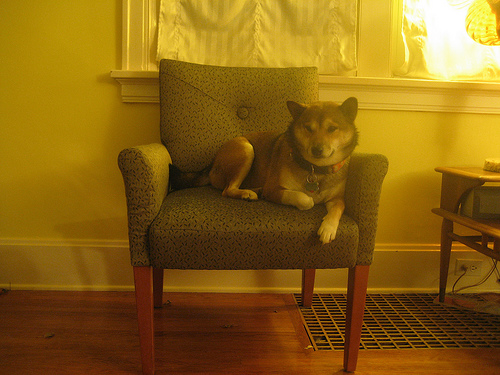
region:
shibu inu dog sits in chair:
[161, 94, 355, 238]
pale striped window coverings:
[161, 2, 356, 70]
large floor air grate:
[293, 288, 496, 352]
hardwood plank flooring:
[2, 291, 498, 372]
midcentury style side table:
[437, 163, 498, 307]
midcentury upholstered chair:
[117, 62, 375, 370]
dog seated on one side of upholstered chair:
[120, 56, 392, 369]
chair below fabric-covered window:
[95, 4, 392, 367]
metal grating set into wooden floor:
[5, 282, 496, 369]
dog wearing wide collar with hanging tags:
[281, 120, 353, 196]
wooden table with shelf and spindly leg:
[426, 154, 496, 311]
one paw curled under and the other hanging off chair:
[265, 175, 346, 246]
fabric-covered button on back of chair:
[158, 59, 320, 180]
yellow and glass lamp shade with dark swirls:
[462, 1, 497, 44]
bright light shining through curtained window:
[400, 2, 497, 80]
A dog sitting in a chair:
[118, 56, 391, 372]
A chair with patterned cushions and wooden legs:
[115, 58, 386, 374]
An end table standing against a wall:
[433, 152, 499, 315]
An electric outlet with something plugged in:
[450, 254, 486, 283]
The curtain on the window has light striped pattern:
[116, 10, 382, 85]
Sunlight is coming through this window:
[371, 10, 499, 92]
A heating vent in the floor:
[276, 281, 499, 364]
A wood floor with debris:
[1, 273, 338, 374]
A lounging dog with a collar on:
[167, 98, 366, 245]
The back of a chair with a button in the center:
[143, 56, 328, 181]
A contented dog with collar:
[168, 95, 364, 241]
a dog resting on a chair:
[109, 55, 390, 371]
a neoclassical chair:
[108, 55, 393, 374]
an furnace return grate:
[280, 275, 497, 362]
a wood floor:
[2, 281, 309, 371]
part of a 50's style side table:
[430, 145, 495, 330]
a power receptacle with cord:
[436, 258, 493, 296]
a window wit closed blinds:
[99, 26, 364, 112]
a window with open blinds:
[378, 24, 496, 99]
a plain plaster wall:
[5, 23, 109, 231]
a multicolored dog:
[167, 98, 359, 243]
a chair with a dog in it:
[114, 55, 391, 374]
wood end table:
[430, 152, 498, 305]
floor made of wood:
[3, 283, 496, 370]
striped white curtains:
[151, 0, 364, 84]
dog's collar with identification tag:
[287, 142, 351, 195]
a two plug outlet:
[453, 254, 484, 280]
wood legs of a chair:
[127, 255, 368, 372]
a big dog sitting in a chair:
[135, 60, 387, 240]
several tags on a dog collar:
[300, 165, 326, 195]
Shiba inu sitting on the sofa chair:
[164, 92, 364, 245]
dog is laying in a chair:
[163, 90, 358, 249]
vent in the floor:
[279, 279, 498, 355]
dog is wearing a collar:
[289, 141, 354, 176]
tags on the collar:
[296, 158, 330, 198]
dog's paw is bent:
[274, 183, 323, 216]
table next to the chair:
[353, 140, 499, 322]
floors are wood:
[5, 281, 140, 371]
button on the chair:
[230, 101, 256, 122]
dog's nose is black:
[309, 144, 327, 157]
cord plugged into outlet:
[451, 259, 478, 292]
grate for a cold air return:
[290, 289, 499, 352]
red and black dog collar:
[293, 140, 352, 175]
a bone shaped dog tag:
[301, 179, 322, 195]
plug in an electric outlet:
[455, 255, 482, 278]